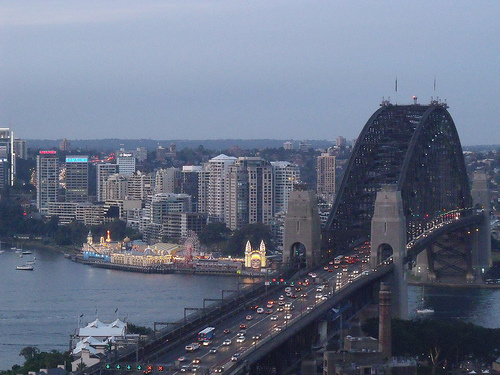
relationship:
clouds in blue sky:
[0, 0, 500, 146] [6, 5, 494, 163]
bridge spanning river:
[79, 102, 487, 370] [3, 245, 498, 373]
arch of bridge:
[321, 100, 473, 256] [74, 200, 491, 373]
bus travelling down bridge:
[196, 324, 215, 340] [136, 99, 484, 368]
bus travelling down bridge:
[333, 254, 346, 266] [136, 99, 484, 368]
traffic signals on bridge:
[106, 333, 181, 373] [82, 131, 479, 368]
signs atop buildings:
[27, 142, 89, 164] [33, 145, 93, 229]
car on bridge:
[208, 345, 218, 354] [79, 102, 487, 370]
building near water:
[240, 226, 269, 270] [3, 243, 267, 358]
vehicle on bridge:
[270, 314, 278, 320] [79, 102, 487, 370]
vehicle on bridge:
[265, 311, 280, 325] [79, 102, 487, 370]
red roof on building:
[37, 144, 59, 160] [28, 145, 62, 218]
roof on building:
[209, 149, 241, 170] [197, 142, 237, 243]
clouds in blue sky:
[0, 0, 500, 146] [1, 0, 498, 146]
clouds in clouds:
[23, 8, 109, 38] [0, 0, 500, 146]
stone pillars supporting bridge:
[368, 185, 404, 264] [190, 216, 407, 368]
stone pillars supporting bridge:
[280, 176, 326, 266] [190, 216, 407, 368]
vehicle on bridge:
[270, 314, 278, 320] [158, 178, 418, 373]